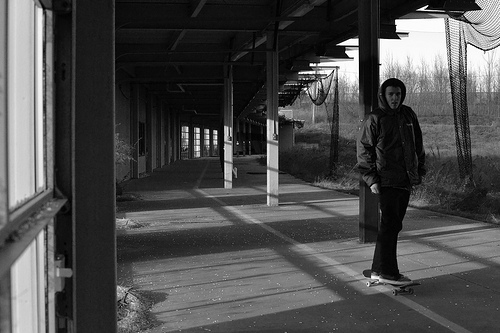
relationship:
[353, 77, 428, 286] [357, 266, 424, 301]
guy on skateboard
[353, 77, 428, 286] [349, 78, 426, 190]
guy wears jacket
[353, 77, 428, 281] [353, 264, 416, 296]
guy on skateboard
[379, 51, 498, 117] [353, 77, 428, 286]
tree behind guy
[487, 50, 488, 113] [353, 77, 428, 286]
tree behind guy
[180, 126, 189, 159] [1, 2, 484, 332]
window to building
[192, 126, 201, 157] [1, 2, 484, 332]
window to building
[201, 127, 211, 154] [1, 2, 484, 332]
window to building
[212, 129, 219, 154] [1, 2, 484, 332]
window to building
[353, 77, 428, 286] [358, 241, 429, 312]
guy riding skateboard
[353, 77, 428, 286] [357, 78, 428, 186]
guy wearing jacket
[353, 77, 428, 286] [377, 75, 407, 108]
guy wearing hood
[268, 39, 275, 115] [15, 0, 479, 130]
post supporting platform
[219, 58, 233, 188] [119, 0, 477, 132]
wooden post supporting roof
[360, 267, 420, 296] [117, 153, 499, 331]
skateboard in ground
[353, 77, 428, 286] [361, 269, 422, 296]
guy on skateboard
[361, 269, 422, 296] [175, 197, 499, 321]
skateboard on sidewalk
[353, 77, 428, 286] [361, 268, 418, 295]
guy rides skateboard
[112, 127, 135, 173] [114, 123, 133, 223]
bush has no leaves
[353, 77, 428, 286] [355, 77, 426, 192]
guy has jacket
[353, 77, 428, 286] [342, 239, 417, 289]
guy wearing shoes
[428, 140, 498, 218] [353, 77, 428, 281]
weeds behind guy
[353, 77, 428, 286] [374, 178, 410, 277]
guy wearing pants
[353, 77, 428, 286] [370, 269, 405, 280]
guy wearing shoe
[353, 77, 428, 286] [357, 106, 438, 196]
guy wearing jacket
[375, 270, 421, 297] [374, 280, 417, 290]
shoe has sole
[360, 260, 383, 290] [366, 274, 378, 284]
shoe has sole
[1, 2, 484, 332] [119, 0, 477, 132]
building has roof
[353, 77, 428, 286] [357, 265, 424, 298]
guy to skateboard